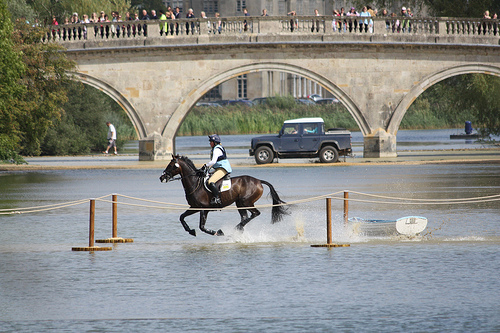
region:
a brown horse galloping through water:
[129, 118, 299, 270]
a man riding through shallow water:
[146, 118, 298, 270]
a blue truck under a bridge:
[234, 108, 354, 183]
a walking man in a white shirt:
[92, 111, 122, 158]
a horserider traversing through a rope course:
[79, 123, 366, 278]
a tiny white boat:
[337, 201, 428, 248]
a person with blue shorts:
[191, 119, 238, 200]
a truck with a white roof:
[240, 102, 360, 169]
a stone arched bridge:
[50, 58, 488, 163]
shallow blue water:
[68, 263, 435, 320]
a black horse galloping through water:
[158, 133, 293, 243]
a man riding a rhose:
[159, 130, 289, 239]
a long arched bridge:
[35, 10, 496, 156]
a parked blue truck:
[248, 111, 354, 167]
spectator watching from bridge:
[183, 4, 197, 36]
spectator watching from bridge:
[195, 9, 211, 34]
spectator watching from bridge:
[237, 5, 252, 30]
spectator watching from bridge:
[283, 7, 295, 27]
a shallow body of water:
[0, 111, 498, 328]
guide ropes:
[2, 194, 497, 249]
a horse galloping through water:
[81, 78, 319, 300]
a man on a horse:
[151, 112, 293, 263]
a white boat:
[343, 198, 448, 260]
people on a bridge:
[6, 7, 498, 166]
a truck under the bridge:
[241, 112, 363, 164]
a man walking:
[70, 104, 132, 176]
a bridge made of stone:
[16, 15, 498, 160]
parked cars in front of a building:
[151, 3, 364, 136]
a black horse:
[141, 154, 296, 248]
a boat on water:
[296, 146, 481, 280]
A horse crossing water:
[142, 134, 307, 251]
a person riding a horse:
[149, 127, 280, 257]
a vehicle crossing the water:
[243, 111, 361, 178]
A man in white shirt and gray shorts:
[89, 110, 131, 162]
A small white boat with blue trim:
[347, 206, 438, 251]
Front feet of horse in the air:
[168, 203, 238, 241]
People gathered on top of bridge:
[41, 4, 478, 54]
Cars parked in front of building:
[202, 85, 346, 116]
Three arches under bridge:
[34, 60, 498, 177]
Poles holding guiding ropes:
[66, 192, 423, 259]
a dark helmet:
[204, 127, 221, 144]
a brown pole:
[70, 197, 105, 254]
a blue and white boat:
[345, 207, 427, 235]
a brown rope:
[328, 191, 498, 206]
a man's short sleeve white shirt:
[104, 125, 119, 141]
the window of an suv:
[303, 124, 319, 133]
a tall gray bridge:
[36, 22, 498, 161]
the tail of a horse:
[252, 181, 295, 221]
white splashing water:
[230, 217, 363, 242]